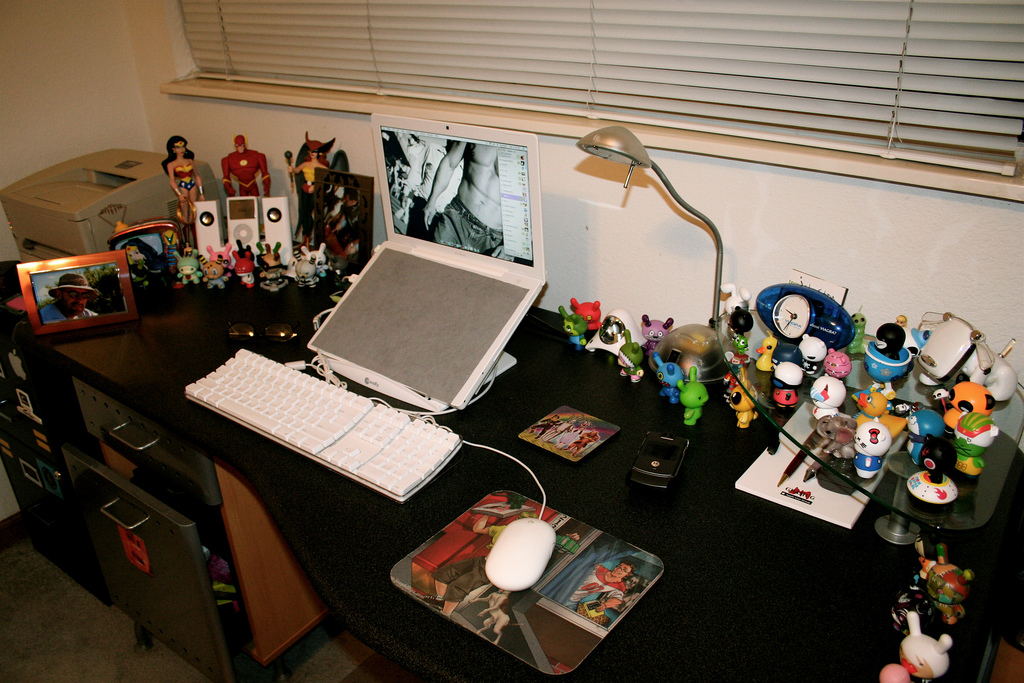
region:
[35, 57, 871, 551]
this is an office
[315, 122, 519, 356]
this is a laptop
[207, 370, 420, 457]
the keyboard is white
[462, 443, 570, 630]
the mouse is wired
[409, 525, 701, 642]
the mouse is white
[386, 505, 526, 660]
this is a mouse pad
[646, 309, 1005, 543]
these are figurines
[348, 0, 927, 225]
these are window blinds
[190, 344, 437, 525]
white keyboard on table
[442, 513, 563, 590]
white mouse on pad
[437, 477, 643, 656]
mousepad on black table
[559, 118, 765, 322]
grey lamp on table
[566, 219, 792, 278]
white wall behind laptop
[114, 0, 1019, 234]
white blind on window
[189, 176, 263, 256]
white iPod in dock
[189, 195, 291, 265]
speakers next to iPod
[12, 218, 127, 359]
brown frame with picture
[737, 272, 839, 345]
blue and white clock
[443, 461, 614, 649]
a view of mouse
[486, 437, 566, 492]
a view of wire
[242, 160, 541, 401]
a view of laptop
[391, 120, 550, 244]
a view of screen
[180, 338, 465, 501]
the keyboard is white on the desk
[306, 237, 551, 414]
the monitor is leaning backwards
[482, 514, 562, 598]
the white mouse is on a pad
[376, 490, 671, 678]
the pad has a colorful picture on it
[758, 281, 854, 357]
a clock is on the desk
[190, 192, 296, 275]
white speakers are on the desk corner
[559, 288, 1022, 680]
objects are scattered over the desk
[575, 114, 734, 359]
a gooseneck lamp is on the desk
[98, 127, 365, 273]
large figures are standing on the corner of the desk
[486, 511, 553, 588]
white mouse on mousepad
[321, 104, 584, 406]
white laptop on the desk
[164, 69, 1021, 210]
ledge of the window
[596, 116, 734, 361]
silver lamp on the desk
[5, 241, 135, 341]
picture frame on the desk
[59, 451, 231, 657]
open drawer on the desk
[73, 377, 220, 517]
top drawer on the desk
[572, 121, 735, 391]
A lamp providing light for the desk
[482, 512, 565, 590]
The mouse used on the computer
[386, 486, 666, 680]
The mousepad used to help the mouse work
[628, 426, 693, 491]
A flip-style cellphone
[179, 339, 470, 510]
The keyboard for a computer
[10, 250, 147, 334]
A photo of a man in a frame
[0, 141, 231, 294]
A printer used to print things from the computer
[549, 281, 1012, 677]
Action figures sitting on the desk looking in different directions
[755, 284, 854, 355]
A clock used to tell time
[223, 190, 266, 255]
An Ipod in an Ipod stand to play music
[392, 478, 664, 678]
white mouse on colorful mousepad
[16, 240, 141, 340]
photograph inside an orange frame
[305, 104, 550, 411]
white laptop with grey cover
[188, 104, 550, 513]
white keyboard in front of laptop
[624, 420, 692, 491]
closed black flip phone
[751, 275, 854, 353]
blue alarm clock with white analog clock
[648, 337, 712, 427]
green figurine next to blue figurine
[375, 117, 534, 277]
shirtless man on laptop screen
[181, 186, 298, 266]
mp3 player between white speakers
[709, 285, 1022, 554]
small figurines on top of glass shelf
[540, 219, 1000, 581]
these are lots of toys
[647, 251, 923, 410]
these are figurines